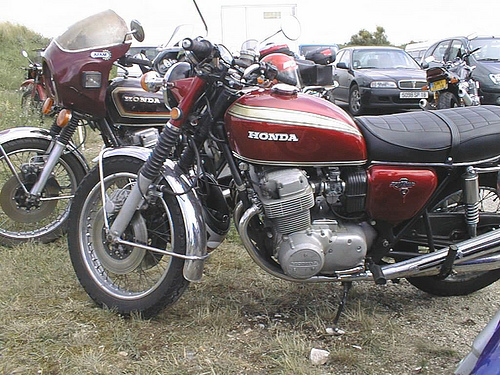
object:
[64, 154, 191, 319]
tire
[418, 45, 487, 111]
cycle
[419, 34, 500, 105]
car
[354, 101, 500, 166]
seat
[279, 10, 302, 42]
mirror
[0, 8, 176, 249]
cycle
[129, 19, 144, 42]
mirror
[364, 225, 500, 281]
pipe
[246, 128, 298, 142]
brand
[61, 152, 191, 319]
wheels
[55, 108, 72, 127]
lights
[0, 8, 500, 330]
lot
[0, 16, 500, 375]
grass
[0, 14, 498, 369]
area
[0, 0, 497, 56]
sky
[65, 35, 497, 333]
bike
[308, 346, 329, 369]
rock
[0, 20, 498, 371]
ground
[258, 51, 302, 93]
helmet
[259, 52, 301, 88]
shield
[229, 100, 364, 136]
stripe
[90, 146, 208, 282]
fender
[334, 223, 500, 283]
muffler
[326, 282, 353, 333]
kick stand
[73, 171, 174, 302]
spokes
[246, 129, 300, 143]
honda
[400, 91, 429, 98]
license plate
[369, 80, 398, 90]
headlight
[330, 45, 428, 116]
car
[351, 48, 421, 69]
window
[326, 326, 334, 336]
rock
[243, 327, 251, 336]
rock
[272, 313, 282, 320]
rock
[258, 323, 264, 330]
rock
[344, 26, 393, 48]
leaves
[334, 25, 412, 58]
tree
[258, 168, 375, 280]
motor